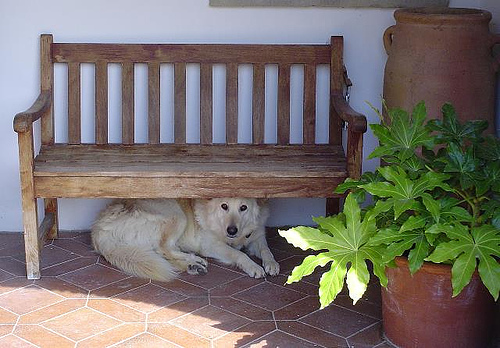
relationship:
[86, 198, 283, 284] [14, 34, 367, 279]
dog hiding under bench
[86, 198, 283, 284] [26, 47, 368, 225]
dog under bench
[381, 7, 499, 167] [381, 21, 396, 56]
pot with handle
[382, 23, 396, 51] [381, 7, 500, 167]
handle on pot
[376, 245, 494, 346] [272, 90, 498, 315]
pot for plant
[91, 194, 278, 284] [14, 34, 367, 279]
dog under bench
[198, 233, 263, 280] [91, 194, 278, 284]
leg of dog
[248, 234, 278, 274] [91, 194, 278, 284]
leg of dog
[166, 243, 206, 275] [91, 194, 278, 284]
leg of dog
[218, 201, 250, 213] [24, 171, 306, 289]
eyes of dog